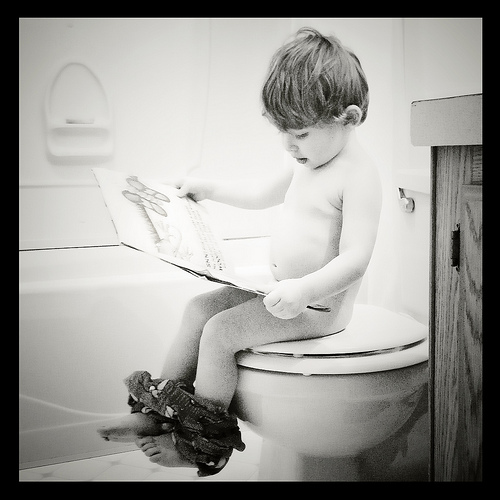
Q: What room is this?
A: It is a bathroom.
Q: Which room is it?
A: It is a bathroom.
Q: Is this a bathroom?
A: Yes, it is a bathroom.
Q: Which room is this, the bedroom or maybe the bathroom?
A: It is the bathroom.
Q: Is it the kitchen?
A: No, it is the bathroom.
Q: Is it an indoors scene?
A: Yes, it is indoors.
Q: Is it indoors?
A: Yes, it is indoors.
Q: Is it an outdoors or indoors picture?
A: It is indoors.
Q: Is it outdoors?
A: No, it is indoors.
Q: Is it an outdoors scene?
A: No, it is indoors.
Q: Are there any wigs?
A: No, there are no wigs.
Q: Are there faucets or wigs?
A: No, there are no wigs or faucets.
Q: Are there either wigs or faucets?
A: No, there are no wigs or faucets.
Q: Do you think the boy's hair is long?
A: Yes, the hair is long.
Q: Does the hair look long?
A: Yes, the hair is long.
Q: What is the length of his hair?
A: The hair is long.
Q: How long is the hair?
A: The hair is long.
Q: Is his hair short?
A: No, the hair is long.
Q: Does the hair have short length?
A: No, the hair is long.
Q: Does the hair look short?
A: No, the hair is long.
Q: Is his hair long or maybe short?
A: The hair is long.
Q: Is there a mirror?
A: No, there are no mirrors.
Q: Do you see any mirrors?
A: No, there are no mirrors.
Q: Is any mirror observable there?
A: No, there are no mirrors.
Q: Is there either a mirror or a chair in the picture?
A: No, there are no mirrors or chairs.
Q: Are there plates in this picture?
A: No, there are no plates.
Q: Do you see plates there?
A: No, there are no plates.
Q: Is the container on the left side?
A: Yes, the container is on the left of the image.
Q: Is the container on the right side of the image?
A: No, the container is on the left of the image.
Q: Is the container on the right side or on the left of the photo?
A: The container is on the left of the image.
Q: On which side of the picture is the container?
A: The container is on the left of the image.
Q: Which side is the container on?
A: The container is on the left of the image.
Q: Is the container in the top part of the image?
A: Yes, the container is in the top of the image.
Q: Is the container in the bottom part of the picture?
A: No, the container is in the top of the image.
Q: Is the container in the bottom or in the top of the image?
A: The container is in the top of the image.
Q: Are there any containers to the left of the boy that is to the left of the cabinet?
A: Yes, there is a container to the left of the boy.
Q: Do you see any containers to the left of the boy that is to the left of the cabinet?
A: Yes, there is a container to the left of the boy.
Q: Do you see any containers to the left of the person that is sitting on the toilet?
A: Yes, there is a container to the left of the boy.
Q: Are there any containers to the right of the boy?
A: No, the container is to the left of the boy.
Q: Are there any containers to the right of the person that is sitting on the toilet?
A: No, the container is to the left of the boy.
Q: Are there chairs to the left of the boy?
A: No, there is a container to the left of the boy.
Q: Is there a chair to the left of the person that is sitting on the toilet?
A: No, there is a container to the left of the boy.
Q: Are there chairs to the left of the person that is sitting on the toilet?
A: No, there is a container to the left of the boy.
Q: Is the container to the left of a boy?
A: Yes, the container is to the left of a boy.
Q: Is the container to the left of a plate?
A: No, the container is to the left of a boy.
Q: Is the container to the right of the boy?
A: No, the container is to the left of the boy.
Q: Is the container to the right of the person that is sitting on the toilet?
A: No, the container is to the left of the boy.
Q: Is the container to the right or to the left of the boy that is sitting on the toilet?
A: The container is to the left of the boy.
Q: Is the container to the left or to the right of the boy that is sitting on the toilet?
A: The container is to the left of the boy.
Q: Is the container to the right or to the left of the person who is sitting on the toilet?
A: The container is to the left of the boy.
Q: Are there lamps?
A: No, there are no lamps.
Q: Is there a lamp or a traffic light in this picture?
A: No, there are no lamps or traffic lights.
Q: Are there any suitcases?
A: No, there are no suitcases.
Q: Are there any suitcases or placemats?
A: No, there are no suitcases or placemats.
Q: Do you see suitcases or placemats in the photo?
A: No, there are no suitcases or placemats.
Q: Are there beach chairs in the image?
A: No, there are no beach chairs.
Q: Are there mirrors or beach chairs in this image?
A: No, there are no beach chairs or mirrors.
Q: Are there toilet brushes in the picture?
A: No, there are no toilet brushes.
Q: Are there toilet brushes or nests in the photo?
A: No, there are no toilet brushes or nests.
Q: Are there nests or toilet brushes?
A: No, there are no toilet brushes or nests.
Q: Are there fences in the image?
A: No, there are no fences.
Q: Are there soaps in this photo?
A: Yes, there is a soap.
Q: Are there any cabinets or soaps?
A: Yes, there is a soap.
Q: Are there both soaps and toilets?
A: Yes, there are both a soap and a toilet.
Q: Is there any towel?
A: No, there are no towels.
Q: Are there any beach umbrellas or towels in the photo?
A: No, there are no towels or beach umbrellas.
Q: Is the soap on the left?
A: Yes, the soap is on the left of the image.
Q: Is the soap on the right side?
A: No, the soap is on the left of the image.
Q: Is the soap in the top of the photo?
A: Yes, the soap is in the top of the image.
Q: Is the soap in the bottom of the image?
A: No, the soap is in the top of the image.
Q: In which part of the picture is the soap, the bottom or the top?
A: The soap is in the top of the image.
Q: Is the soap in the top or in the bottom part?
A: The soap is in the top of the image.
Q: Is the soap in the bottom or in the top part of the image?
A: The soap is in the top of the image.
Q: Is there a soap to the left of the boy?
A: Yes, there is a soap to the left of the boy.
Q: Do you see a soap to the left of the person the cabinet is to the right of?
A: Yes, there is a soap to the left of the boy.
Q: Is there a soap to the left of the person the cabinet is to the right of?
A: Yes, there is a soap to the left of the boy.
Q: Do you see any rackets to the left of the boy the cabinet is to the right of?
A: No, there is a soap to the left of the boy.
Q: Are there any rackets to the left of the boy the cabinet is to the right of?
A: No, there is a soap to the left of the boy.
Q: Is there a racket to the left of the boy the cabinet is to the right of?
A: No, there is a soap to the left of the boy.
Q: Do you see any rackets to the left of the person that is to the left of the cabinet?
A: No, there is a soap to the left of the boy.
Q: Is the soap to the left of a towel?
A: No, the soap is to the left of a boy.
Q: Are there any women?
A: No, there are no women.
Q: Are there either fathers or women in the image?
A: No, there are no women or fathers.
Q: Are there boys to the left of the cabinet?
A: Yes, there is a boy to the left of the cabinet.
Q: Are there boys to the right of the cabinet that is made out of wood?
A: No, the boy is to the left of the cabinet.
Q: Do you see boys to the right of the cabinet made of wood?
A: No, the boy is to the left of the cabinet.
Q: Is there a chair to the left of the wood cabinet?
A: No, there is a boy to the left of the cabinet.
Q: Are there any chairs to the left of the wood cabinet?
A: No, there is a boy to the left of the cabinet.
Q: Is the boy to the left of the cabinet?
A: Yes, the boy is to the left of the cabinet.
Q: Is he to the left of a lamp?
A: No, the boy is to the left of the cabinet.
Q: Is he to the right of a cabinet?
A: No, the boy is to the left of a cabinet.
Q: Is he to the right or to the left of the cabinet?
A: The boy is to the left of the cabinet.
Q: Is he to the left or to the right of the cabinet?
A: The boy is to the left of the cabinet.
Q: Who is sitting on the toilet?
A: The boy is sitting on the toilet.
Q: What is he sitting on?
A: The boy is sitting on the toilet.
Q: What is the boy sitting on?
A: The boy is sitting on the toilet.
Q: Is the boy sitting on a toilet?
A: Yes, the boy is sitting on a toilet.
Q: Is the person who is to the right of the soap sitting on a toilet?
A: Yes, the boy is sitting on a toilet.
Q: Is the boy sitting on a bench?
A: No, the boy is sitting on a toilet.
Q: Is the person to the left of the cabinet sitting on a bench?
A: No, the boy is sitting on a toilet.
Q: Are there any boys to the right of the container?
A: Yes, there is a boy to the right of the container.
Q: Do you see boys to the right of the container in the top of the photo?
A: Yes, there is a boy to the right of the container.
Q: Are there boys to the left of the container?
A: No, the boy is to the right of the container.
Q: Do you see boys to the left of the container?
A: No, the boy is to the right of the container.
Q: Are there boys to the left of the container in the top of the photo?
A: No, the boy is to the right of the container.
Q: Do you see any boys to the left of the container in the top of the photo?
A: No, the boy is to the right of the container.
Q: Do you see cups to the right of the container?
A: No, there is a boy to the right of the container.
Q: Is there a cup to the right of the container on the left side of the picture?
A: No, there is a boy to the right of the container.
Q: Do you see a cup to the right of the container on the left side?
A: No, there is a boy to the right of the container.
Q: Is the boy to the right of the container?
A: Yes, the boy is to the right of the container.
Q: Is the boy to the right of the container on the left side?
A: Yes, the boy is to the right of the container.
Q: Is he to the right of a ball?
A: No, the boy is to the right of the container.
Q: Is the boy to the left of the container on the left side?
A: No, the boy is to the right of the container.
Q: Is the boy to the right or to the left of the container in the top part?
A: The boy is to the right of the container.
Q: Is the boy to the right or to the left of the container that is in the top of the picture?
A: The boy is to the right of the container.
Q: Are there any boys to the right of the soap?
A: Yes, there is a boy to the right of the soap.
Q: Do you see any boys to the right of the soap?
A: Yes, there is a boy to the right of the soap.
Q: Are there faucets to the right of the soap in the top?
A: No, there is a boy to the right of the soap.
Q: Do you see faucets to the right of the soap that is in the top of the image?
A: No, there is a boy to the right of the soap.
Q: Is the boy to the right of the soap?
A: Yes, the boy is to the right of the soap.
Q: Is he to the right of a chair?
A: No, the boy is to the right of the soap.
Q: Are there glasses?
A: No, there are no glasses.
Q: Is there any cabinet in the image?
A: Yes, there is a cabinet.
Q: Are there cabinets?
A: Yes, there is a cabinet.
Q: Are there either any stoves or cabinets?
A: Yes, there is a cabinet.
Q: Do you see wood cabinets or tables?
A: Yes, there is a wood cabinet.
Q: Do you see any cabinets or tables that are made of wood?
A: Yes, the cabinet is made of wood.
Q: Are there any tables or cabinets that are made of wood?
A: Yes, the cabinet is made of wood.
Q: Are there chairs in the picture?
A: No, there are no chairs.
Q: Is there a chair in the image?
A: No, there are no chairs.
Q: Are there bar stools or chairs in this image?
A: No, there are no chairs or bar stools.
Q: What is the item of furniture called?
A: The piece of furniture is a cabinet.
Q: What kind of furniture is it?
A: The piece of furniture is a cabinet.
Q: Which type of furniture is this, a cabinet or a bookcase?
A: That is a cabinet.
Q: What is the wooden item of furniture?
A: The piece of furniture is a cabinet.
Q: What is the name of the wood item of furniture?
A: The piece of furniture is a cabinet.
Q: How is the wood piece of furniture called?
A: The piece of furniture is a cabinet.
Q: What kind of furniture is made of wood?
A: The furniture is a cabinet.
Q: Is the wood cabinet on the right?
A: Yes, the cabinet is on the right of the image.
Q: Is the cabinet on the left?
A: No, the cabinet is on the right of the image.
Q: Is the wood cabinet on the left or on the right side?
A: The cabinet is on the right of the image.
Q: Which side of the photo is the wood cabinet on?
A: The cabinet is on the right of the image.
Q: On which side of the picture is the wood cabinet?
A: The cabinet is on the right of the image.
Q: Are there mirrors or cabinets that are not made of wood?
A: No, there is a cabinet but it is made of wood.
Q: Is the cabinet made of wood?
A: Yes, the cabinet is made of wood.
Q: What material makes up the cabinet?
A: The cabinet is made of wood.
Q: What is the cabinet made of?
A: The cabinet is made of wood.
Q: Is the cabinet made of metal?
A: No, the cabinet is made of wood.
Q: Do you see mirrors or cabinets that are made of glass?
A: No, there is a cabinet but it is made of wood.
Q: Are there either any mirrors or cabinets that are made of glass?
A: No, there is a cabinet but it is made of wood.